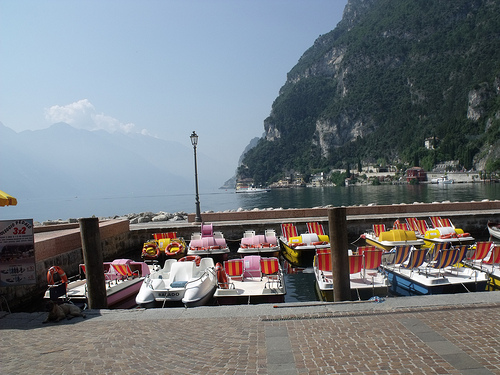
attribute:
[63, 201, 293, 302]
boats — many 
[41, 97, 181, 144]
clouds — white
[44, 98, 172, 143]
clouds — white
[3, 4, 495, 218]
sky — blue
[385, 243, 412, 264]
seat — four, striped, black, gold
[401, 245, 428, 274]
seat — four, striped, black, gold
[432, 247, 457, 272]
seat — four, striped, black, gold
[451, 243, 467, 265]
seat — four, striped, black, gold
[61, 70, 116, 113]
clouds — are white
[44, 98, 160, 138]
cloud — white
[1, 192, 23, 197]
umbrella — yellow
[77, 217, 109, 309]
pole — short 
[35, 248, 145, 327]
boat — white 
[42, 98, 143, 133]
clouds — white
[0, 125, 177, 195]
cloud — white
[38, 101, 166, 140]
cloud — white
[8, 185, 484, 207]
water — body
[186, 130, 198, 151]
lamp — street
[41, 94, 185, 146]
cloud — white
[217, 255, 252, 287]
chair — striped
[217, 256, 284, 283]
seats — red , yellow 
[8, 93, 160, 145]
cloud — white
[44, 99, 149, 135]
clouds — white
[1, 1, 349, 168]
sky — blue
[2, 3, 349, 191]
sky — blue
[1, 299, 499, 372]
pavement — brick